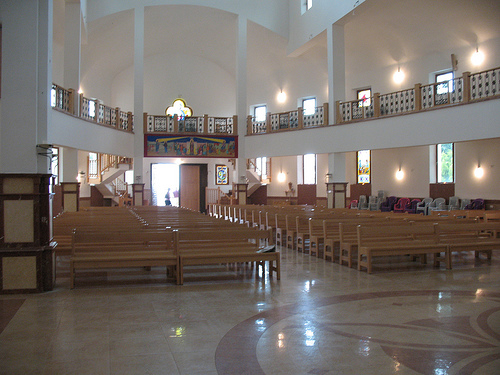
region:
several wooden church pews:
[93, 212, 442, 279]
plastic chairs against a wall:
[346, 190, 471, 210]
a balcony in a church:
[56, 58, 486, 145]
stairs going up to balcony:
[77, 147, 137, 210]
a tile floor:
[198, 301, 404, 371]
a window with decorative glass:
[147, 85, 194, 130]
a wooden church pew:
[65, 225, 281, 276]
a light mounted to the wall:
[387, 156, 415, 181]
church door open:
[141, 157, 211, 203]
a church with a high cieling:
[89, 6, 286, 299]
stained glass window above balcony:
[162, 91, 199, 124]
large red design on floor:
[224, 271, 497, 371]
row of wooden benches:
[50, 192, 283, 287]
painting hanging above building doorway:
[136, 128, 242, 163]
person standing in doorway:
[147, 173, 183, 213]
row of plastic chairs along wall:
[347, 188, 498, 222]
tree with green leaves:
[438, 147, 453, 182]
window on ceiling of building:
[295, 0, 316, 20]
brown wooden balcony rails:
[47, 86, 134, 134]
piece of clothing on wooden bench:
[248, 241, 281, 260]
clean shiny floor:
[19, 291, 479, 364]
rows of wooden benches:
[47, 196, 284, 286]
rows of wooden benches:
[205, 195, 490, 270]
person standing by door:
[162, 185, 179, 208]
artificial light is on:
[265, 72, 305, 202]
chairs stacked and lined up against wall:
[352, 179, 492, 224]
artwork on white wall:
[135, 127, 245, 162]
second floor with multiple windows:
[42, 44, 494, 153]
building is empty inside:
[45, 53, 498, 287]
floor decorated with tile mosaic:
[192, 292, 494, 372]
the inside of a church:
[2, 1, 496, 373]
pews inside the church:
[52, 205, 497, 286]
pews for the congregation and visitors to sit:
[54, 205, 496, 287]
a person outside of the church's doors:
[161, 187, 173, 204]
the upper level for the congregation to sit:
[44, 65, 499, 133]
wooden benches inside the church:
[53, 207, 498, 287]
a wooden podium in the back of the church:
[60, 181, 80, 208]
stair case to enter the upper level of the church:
[80, 152, 130, 182]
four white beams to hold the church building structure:
[61, 16, 346, 176]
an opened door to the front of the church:
[150, 162, 201, 208]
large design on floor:
[205, 268, 497, 374]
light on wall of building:
[384, 151, 419, 185]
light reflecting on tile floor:
[157, 283, 356, 363]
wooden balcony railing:
[43, 83, 134, 133]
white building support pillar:
[227, 14, 249, 178]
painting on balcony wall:
[139, 133, 243, 162]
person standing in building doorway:
[153, 183, 178, 210]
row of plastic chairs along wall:
[357, 192, 464, 213]